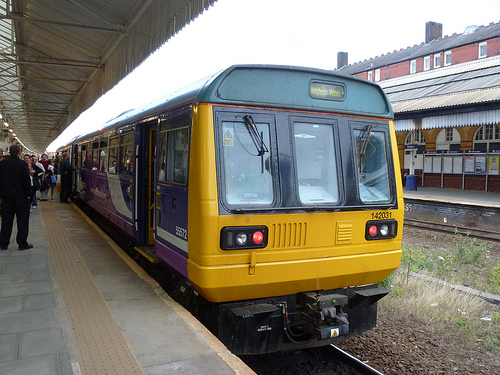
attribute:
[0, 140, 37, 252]
man — pictured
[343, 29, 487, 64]
roof — grey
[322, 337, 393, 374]
metal — pictured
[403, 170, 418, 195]
trash can — blue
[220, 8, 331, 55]
sky — blue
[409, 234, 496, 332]
grass area — pictured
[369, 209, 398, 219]
142031 — train number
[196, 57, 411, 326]
front — yellow, blue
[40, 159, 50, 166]
shirt — red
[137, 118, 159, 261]
door — pictured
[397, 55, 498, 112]
roof — pictured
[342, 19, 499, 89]
wall — red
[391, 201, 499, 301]
tracks — train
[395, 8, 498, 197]
building — pictured